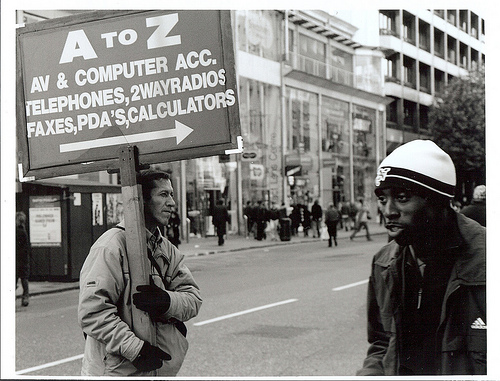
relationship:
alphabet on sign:
[56, 16, 179, 60] [27, 14, 237, 167]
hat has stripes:
[378, 119, 465, 204] [378, 168, 459, 202]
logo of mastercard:
[238, 149, 259, 160] [244, 153, 254, 158]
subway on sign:
[287, 168, 296, 174] [285, 160, 305, 181]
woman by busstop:
[18, 211, 39, 309] [15, 187, 119, 285]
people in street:
[331, 209, 371, 246] [242, 250, 355, 351]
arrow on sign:
[49, 124, 208, 152] [27, 14, 237, 167]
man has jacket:
[365, 129, 478, 375] [375, 244, 487, 343]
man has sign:
[75, 177, 201, 373] [27, 14, 237, 167]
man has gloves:
[75, 177, 201, 373] [127, 281, 172, 374]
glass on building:
[325, 108, 347, 150] [285, 71, 383, 209]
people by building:
[239, 191, 315, 238] [285, 71, 383, 209]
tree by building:
[428, 64, 486, 186] [378, 18, 479, 114]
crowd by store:
[194, 196, 376, 242] [238, 82, 277, 202]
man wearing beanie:
[365, 129, 478, 375] [378, 119, 465, 204]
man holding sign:
[75, 177, 201, 373] [27, 14, 237, 167]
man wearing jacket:
[75, 177, 201, 373] [85, 242, 197, 365]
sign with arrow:
[27, 14, 237, 167] [49, 124, 208, 152]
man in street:
[325, 208, 336, 250] [242, 250, 355, 351]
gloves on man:
[127, 281, 172, 374] [365, 129, 478, 375]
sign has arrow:
[27, 14, 237, 167] [49, 124, 208, 152]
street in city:
[242, 250, 355, 351] [33, 20, 460, 198]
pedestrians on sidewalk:
[208, 190, 367, 216] [183, 232, 272, 254]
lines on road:
[219, 281, 348, 326] [199, 263, 319, 375]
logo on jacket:
[469, 315, 486, 333] [375, 244, 487, 343]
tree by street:
[428, 64, 486, 186] [242, 250, 355, 351]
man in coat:
[365, 129, 478, 375] [443, 234, 480, 361]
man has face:
[365, 129, 478, 375] [377, 195, 415, 232]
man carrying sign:
[75, 177, 201, 373] [27, 14, 237, 167]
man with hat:
[365, 129, 478, 375] [378, 119, 465, 204]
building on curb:
[54, 183, 134, 275] [20, 265, 85, 307]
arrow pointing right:
[49, 124, 208, 152] [168, 121, 199, 147]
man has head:
[75, 177, 201, 373] [138, 164, 188, 229]